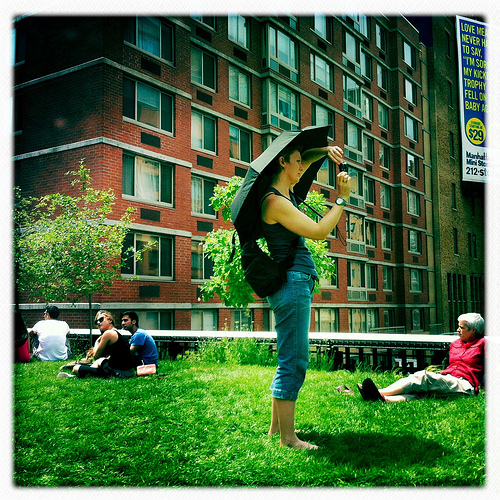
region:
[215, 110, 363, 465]
A WOMAN TAKING A PHOTO WITH HER CELL PHONE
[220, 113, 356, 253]
A BLACK UMBRELLA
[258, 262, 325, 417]
A PAIR OF BLUE JEAN CAPRI PANTS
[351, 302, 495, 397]
A MAN WITH GRAY HAIR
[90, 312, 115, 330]
A PAIR OF BLACK SUNGLASSES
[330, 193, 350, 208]
A GREEN WRISTWATCH WITH A WHITE FACE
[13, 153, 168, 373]
TWO TREES IN THE GRASS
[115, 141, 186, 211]
A WINDOW WITH GREEN AND WHITE CURTAINS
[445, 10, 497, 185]
A BLUE, WHITE AND YELLOW SIGN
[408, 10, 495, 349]
A TAN COLORED BUILDING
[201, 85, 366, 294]
a woman with a black umbrella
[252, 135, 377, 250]
a woman taking a picture with a cell phone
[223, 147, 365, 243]
a woman holding a cell phone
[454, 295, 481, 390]
a woman with grey hair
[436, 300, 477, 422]
a woman wearing a red shirt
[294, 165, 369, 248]
a green watch on a woman's wrist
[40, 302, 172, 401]
three people sitting on the ground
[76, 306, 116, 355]
a woman wearing sunglasses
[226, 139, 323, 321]
a woman with a black purse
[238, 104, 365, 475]
a woman wearing blue jeans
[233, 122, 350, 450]
Woman standing on grass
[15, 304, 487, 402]
People sitting on the grass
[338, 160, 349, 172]
Camera in the woman's hands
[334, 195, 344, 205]
Watch on the woman's wrist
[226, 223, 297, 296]
Bag on the woman's back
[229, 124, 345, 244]
Umbrella on the woman's shoulder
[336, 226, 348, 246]
String on the umbrella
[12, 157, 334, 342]
Trees growing in the park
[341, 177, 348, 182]
Ring on the woman's finger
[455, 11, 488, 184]
Banner in the air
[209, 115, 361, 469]
a young woman holding an umbrella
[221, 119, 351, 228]
a black umbrella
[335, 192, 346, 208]
a watch on a young woman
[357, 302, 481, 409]
an older man sitting in the grass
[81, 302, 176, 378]
a young couple sitting in the grass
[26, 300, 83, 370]
a young man in a white shirt sitting in the grass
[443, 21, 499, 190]
An advertising sign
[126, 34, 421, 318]
a large apartment building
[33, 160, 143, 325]
a tree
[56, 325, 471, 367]
A guard rail on a ledge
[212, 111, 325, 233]
the black colored umbrella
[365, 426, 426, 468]
the green colored grass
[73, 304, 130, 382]
a girl with black colored t shirt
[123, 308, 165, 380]
the man with blue colored t shirt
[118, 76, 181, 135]
the glass window of an apartment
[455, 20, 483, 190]
the banner on the walls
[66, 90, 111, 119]
the red colored bricks on the wall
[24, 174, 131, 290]
the green colored trees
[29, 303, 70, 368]
the man with white colored t shirt sitting on the grass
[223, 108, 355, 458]
a women standing on the grass and taking photograph